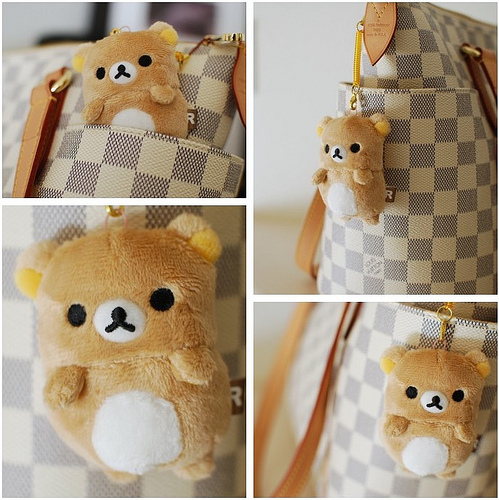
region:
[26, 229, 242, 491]
the bear is brown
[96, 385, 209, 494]
bear's belly is white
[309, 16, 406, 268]
the bear is hanging on the bag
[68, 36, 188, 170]
the bear is inside the pocket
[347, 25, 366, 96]
the string is yellow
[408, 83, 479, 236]
the bag's design is checkered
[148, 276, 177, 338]
the bear's eye is black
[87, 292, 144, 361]
the bear's nose is black and white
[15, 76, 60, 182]
the bag's strap is brown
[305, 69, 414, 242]
the bear is small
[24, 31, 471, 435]
Four pictures are joined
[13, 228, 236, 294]
Teddy has yellow ears.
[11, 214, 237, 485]
Teddy is brown in color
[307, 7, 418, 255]
Teddy is tied to the handbag zip.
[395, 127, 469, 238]
Handbag color is white and grey.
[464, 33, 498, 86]
Handle is brown in color.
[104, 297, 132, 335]
Teddy has black nose.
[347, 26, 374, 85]
rope color is yellow.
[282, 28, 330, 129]
Wall is white in color.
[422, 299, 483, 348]
Hanging ring is golden in color.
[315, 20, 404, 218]
a stuffed bear hanging off of a purse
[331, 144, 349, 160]
the nose of a stuffed bear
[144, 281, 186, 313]
the eye of a stuffed animal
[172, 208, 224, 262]
the ear of a stuffed animal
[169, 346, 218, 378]
the paw of a stuffed animal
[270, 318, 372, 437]
strap of a purse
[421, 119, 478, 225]
checkered design on a purse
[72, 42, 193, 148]
a stuffed bear in a purse pocket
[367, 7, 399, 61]
brown leather on a purse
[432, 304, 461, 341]
a gold colored chain link on a purse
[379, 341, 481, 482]
the teddy bear is brown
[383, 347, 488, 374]
the teddy bear has yellow ears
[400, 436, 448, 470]
the bear has a white belly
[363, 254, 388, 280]
the bag is louis vuitton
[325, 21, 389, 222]
the bear hangs from the bag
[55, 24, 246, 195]
the bear is in the pocket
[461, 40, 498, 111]
the bag has straps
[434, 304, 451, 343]
the bear has a gold holder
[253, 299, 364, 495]
the strap is beige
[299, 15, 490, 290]
the bag has squares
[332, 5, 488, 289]
grey and tan checked purse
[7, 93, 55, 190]
light brown purse strap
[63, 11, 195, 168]
small stuffed animal protruding from purse pocket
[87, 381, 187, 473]
white circle on stuffed animal's abdomen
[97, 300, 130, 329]
black detail on stuffed animal's nose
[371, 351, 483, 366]
yellow sections on bottom of stuffed animal's ears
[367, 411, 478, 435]
stuffed animal's paws are beneath its head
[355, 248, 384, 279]
grey words printed on purse's side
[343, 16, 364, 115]
animal hung from purse by yellow strap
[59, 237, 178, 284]
stuffed animal's predominant color is light brown